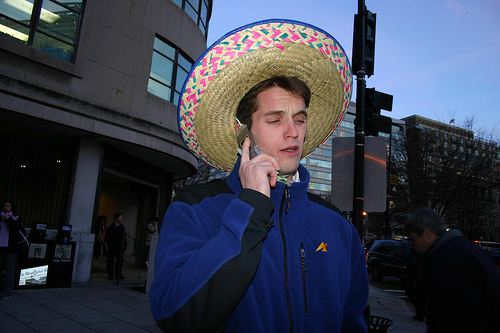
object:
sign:
[328, 135, 389, 213]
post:
[353, 0, 364, 237]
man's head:
[236, 79, 313, 175]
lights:
[0, 0, 62, 47]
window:
[1, 0, 92, 80]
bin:
[367, 312, 394, 331]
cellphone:
[233, 122, 262, 159]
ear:
[231, 120, 242, 132]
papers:
[28, 244, 48, 257]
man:
[147, 18, 372, 330]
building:
[396, 114, 498, 204]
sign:
[355, 74, 366, 225]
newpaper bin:
[19, 216, 56, 294]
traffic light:
[353, 0, 383, 255]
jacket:
[104, 223, 129, 256]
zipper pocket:
[291, 227, 345, 318]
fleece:
[179, 211, 203, 236]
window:
[144, 34, 199, 108]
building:
[2, 0, 215, 280]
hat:
[178, 12, 351, 169]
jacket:
[147, 159, 380, 331]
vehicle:
[364, 236, 417, 290]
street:
[366, 242, 499, 302]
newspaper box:
[43, 217, 80, 287]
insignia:
[308, 234, 332, 256]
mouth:
[277, 142, 303, 158]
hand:
[234, 130, 284, 199]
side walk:
[0, 261, 181, 329]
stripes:
[313, 271, 359, 327]